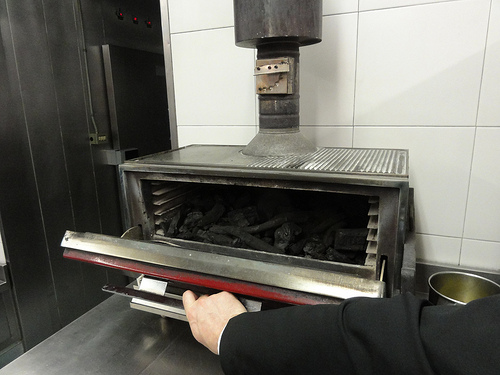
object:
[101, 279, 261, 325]
handle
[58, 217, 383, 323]
door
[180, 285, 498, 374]
man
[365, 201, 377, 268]
racks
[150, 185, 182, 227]
racks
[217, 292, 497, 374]
sleeve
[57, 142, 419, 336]
oven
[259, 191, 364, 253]
sticks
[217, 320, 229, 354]
white shirt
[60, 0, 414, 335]
bowl heater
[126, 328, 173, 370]
metal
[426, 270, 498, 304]
bowl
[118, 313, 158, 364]
ground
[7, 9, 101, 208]
panels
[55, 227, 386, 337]
cooker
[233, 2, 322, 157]
pipe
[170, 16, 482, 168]
white tiles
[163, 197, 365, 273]
charcoal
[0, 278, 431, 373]
counter top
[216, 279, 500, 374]
arm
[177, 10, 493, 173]
wall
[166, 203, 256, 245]
wood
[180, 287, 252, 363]
hand